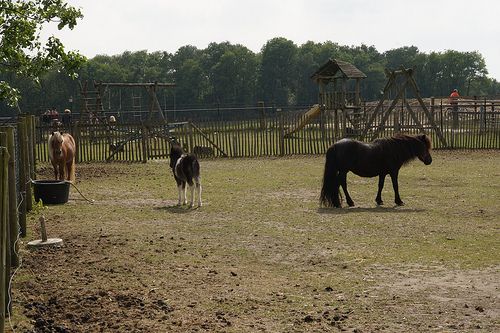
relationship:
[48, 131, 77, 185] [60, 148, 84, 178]
blonde main with a blonde mane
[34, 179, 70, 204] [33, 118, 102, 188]
bucket for horses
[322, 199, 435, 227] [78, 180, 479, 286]
dark shadow on ground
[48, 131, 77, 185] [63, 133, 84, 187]
blonde main with a blonde main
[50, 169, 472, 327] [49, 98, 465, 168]
field inside fence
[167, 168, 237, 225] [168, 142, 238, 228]
legs of horse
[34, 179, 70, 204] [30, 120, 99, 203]
bucket in front of horse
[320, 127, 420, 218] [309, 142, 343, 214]
horse with tail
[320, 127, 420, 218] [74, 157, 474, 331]
horse in pasture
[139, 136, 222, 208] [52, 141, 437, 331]
horse in pasture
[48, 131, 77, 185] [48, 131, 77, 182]
blonde main with blonde mane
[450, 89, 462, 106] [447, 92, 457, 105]
man wearing top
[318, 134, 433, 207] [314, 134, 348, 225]
horse has tail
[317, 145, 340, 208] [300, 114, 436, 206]
horse tail of pony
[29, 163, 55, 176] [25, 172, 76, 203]
hose over container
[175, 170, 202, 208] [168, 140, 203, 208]
legs of horse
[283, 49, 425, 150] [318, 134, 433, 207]
playground behind horse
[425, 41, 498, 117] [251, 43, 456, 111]
tree in woods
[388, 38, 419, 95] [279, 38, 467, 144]
tree in woods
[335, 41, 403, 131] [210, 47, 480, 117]
tree in woods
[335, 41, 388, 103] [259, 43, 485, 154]
tree in woods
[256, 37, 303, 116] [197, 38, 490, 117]
tree in woods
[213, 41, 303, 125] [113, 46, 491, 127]
tree in woods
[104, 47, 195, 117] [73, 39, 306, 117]
tree in woods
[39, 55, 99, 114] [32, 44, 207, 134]
tree in woods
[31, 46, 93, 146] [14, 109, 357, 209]
tree in field